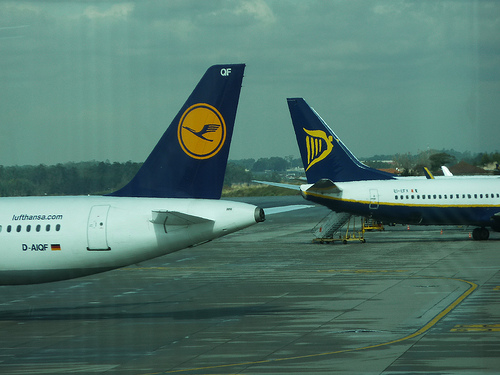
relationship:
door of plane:
[85, 202, 108, 248] [2, 63, 264, 285]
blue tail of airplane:
[104, 62, 246, 197] [1, 189, 237, 281]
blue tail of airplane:
[284, 97, 397, 181] [272, 88, 498, 248]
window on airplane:
[45, 225, 50, 230] [1, 55, 272, 295]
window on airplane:
[32, 223, 47, 240] [1, 55, 272, 295]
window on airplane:
[26, 225, 31, 233] [1, 55, 272, 295]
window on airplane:
[388, 190, 442, 208] [268, 110, 486, 242]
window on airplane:
[393, 194, 400, 201] [251, 94, 499, 243]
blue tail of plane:
[112, 59, 248, 200] [2, 191, 268, 281]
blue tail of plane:
[284, 97, 397, 181] [283, 95, 495, 237]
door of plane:
[367, 190, 379, 210] [251, 97, 496, 241]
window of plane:
[55, 224, 60, 232] [3, 34, 270, 291]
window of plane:
[26, 222, 32, 232] [2, 63, 264, 285]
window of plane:
[403, 189, 421, 203] [271, 116, 490, 253]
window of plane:
[55, 221, 62, 231] [2, 63, 264, 285]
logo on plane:
[181, 122, 221, 142] [2, 63, 264, 285]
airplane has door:
[0, 62, 267, 287] [75, 195, 113, 256]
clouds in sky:
[1, 0, 498, 168] [0, 0, 499, 166]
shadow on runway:
[20, 268, 312, 320] [4, 197, 499, 368]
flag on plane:
[49, 242, 59, 252] [283, 95, 495, 237]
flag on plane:
[49, 242, 59, 252] [2, 63, 264, 285]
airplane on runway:
[0, 62, 267, 287] [4, 197, 499, 368]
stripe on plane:
[303, 190, 499, 207] [251, 97, 496, 241]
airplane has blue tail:
[1, 55, 272, 295] [104, 62, 246, 197]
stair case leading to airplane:
[310, 209, 368, 245] [290, 97, 492, 244]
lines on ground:
[413, 312, 440, 340] [163, 298, 223, 368]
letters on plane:
[215, 62, 232, 81] [2, 63, 264, 285]